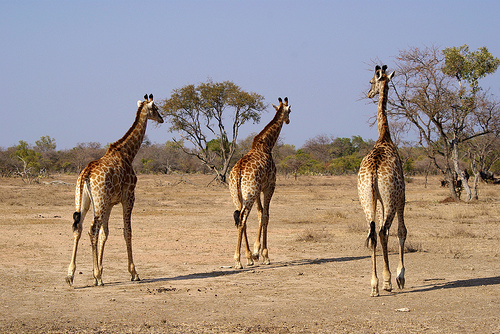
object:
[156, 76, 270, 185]
tree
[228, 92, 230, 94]
leaves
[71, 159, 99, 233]
tail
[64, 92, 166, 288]
giraffe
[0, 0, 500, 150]
sky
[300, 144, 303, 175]
trees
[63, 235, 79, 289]
feet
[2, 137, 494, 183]
bushes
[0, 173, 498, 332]
field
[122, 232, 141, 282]
feet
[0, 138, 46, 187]
shrub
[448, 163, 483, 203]
base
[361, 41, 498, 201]
tree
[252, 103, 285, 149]
mane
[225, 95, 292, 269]
giraffe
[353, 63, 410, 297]
giraffe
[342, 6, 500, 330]
right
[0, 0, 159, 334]
left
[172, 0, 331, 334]
middle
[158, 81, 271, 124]
green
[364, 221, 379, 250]
hair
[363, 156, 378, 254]
tail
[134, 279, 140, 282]
hooves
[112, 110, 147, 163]
necks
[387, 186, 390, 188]
markings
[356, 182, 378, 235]
thighs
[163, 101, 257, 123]
ends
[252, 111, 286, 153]
neck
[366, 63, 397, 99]
head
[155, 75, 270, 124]
shape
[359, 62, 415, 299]
brown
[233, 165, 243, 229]
tail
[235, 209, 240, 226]
end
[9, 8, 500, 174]
background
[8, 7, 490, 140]
blue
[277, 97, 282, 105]
horns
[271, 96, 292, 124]
head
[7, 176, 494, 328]
brown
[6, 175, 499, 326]
dirt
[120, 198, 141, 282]
leg